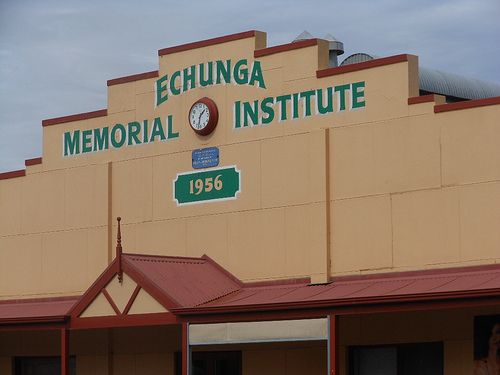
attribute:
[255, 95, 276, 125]
s — letter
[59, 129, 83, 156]
letter — M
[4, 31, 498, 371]
building — yellow, red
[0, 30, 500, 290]
building — brown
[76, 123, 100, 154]
letter — E